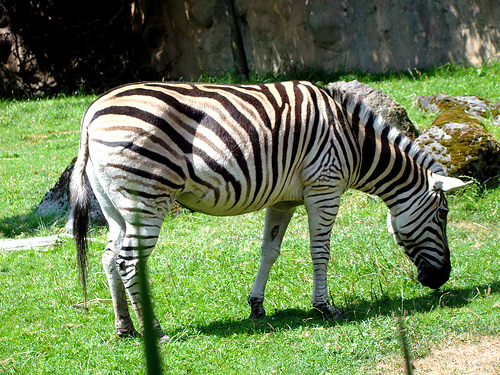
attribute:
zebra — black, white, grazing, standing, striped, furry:
[69, 82, 466, 338]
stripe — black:
[292, 80, 301, 158]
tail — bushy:
[69, 119, 91, 304]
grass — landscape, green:
[7, 226, 498, 374]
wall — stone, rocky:
[1, 0, 498, 99]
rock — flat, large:
[408, 94, 498, 183]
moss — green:
[430, 99, 480, 125]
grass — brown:
[376, 337, 498, 374]